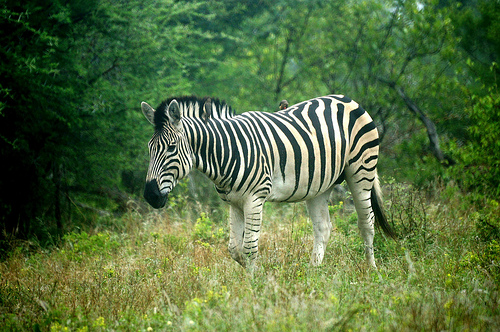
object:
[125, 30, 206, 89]
leaves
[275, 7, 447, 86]
tree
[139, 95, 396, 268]
zebra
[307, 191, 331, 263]
leg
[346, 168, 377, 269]
leg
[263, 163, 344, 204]
belly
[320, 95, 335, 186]
stripe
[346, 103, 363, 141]
stripe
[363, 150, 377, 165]
stripe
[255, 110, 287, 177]
stripe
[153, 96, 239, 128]
hair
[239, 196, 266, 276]
leg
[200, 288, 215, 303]
flowers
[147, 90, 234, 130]
mane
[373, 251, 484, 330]
flowers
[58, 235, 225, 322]
grass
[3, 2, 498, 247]
trees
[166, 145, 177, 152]
eye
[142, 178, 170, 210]
nose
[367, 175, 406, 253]
tail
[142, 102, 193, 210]
head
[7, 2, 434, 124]
lush trees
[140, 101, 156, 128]
ear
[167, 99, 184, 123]
ear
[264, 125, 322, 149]
pattern